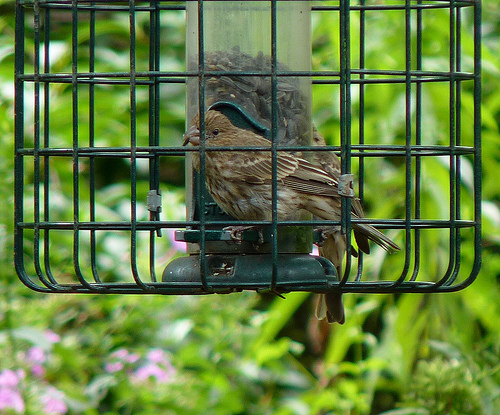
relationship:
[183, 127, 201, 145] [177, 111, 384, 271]
beak of bird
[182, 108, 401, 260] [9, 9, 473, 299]
bird in cage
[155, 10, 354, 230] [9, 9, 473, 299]
door on cage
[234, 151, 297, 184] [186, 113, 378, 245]
feathers of bird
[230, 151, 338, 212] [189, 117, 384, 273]
feathers of bird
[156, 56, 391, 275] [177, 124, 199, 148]
bird has beak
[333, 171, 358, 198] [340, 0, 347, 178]
clip holding green wire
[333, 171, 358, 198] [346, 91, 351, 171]
clip holding wire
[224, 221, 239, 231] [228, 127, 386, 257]
claws of bird